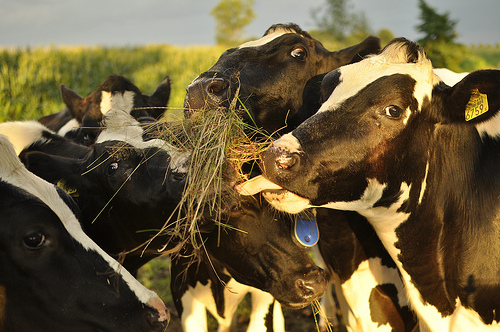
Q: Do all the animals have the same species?
A: Yes, all the animals are cows.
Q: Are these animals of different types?
A: No, all the animals are cows.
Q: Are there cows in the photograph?
A: Yes, there are cows.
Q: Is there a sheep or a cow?
A: Yes, there are cows.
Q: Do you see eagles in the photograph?
A: No, there are no eagles.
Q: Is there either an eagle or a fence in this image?
A: No, there are no eagles or fences.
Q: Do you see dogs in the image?
A: No, there are no dogs.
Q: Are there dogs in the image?
A: No, there are no dogs.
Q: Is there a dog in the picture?
A: No, there are no dogs.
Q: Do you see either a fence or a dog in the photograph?
A: No, there are no dogs or fences.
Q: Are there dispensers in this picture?
A: No, there are no dispensers.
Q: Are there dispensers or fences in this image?
A: No, there are no dispensers or fences.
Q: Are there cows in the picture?
A: Yes, there is a cow.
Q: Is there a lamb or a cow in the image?
A: Yes, there is a cow.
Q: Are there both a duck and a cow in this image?
A: No, there is a cow but no ducks.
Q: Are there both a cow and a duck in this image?
A: No, there is a cow but no ducks.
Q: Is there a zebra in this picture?
A: No, there are no zebras.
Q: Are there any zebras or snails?
A: No, there are no zebras or snails.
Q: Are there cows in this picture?
A: Yes, there is a cow.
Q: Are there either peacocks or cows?
A: Yes, there is a cow.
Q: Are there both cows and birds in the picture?
A: No, there is a cow but no birds.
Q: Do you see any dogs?
A: No, there are no dogs.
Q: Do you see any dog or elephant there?
A: No, there are no dogs or elephants.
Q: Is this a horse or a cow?
A: This is a cow.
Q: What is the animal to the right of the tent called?
A: The animal is a cow.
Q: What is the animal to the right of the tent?
A: The animal is a cow.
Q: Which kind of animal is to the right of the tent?
A: The animal is a cow.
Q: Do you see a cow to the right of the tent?
A: Yes, there is a cow to the right of the tent.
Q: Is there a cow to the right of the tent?
A: Yes, there is a cow to the right of the tent.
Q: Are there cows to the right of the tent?
A: Yes, there is a cow to the right of the tent.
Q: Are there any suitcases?
A: No, there are no suitcases.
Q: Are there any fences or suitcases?
A: No, there are no suitcases or fences.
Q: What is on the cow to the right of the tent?
A: The tag is on the cow.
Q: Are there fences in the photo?
A: No, there are no fences.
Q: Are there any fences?
A: No, there are no fences.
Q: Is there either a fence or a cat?
A: No, there are no fences or cats.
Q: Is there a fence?
A: No, there are no fences.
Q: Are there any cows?
A: Yes, there are cows.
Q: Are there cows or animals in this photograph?
A: Yes, there are cows.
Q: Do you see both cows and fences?
A: No, there are cows but no fences.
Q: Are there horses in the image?
A: No, there are no horses.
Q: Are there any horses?
A: No, there are no horses.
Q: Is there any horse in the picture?
A: No, there are no horses.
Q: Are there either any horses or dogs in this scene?
A: No, there are no horses or dogs.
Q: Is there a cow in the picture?
A: Yes, there is a cow.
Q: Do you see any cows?
A: Yes, there is a cow.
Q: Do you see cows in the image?
A: Yes, there is a cow.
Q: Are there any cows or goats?
A: Yes, there is a cow.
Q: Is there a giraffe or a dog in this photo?
A: No, there are no dogs or giraffes.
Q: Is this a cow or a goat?
A: This is a cow.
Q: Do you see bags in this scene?
A: No, there are no bags.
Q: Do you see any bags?
A: No, there are no bags.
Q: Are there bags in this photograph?
A: No, there are no bags.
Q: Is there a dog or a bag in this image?
A: No, there are no bags or dogs.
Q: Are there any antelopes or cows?
A: Yes, there is a cow.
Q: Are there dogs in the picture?
A: No, there are no dogs.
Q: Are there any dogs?
A: No, there are no dogs.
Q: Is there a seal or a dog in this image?
A: No, there are no dogs or seals.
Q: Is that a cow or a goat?
A: That is a cow.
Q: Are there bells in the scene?
A: No, there are no bells.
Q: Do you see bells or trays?
A: No, there are no bells or trays.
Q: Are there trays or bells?
A: No, there are no bells or trays.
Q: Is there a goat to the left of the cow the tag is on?
A: No, there is a tent to the left of the cow.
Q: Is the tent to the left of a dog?
A: No, the tent is to the left of the cow.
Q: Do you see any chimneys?
A: No, there are no chimneys.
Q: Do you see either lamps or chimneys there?
A: No, there are no chimneys or lamps.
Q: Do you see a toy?
A: No, there are no toys.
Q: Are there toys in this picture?
A: No, there are no toys.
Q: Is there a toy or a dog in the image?
A: No, there are no toys or dogs.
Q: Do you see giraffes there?
A: No, there are no giraffes.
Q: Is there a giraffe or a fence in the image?
A: No, there are no giraffes or fences.